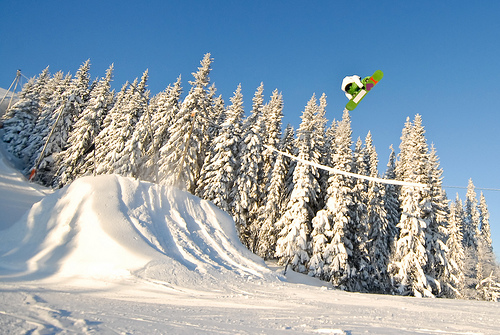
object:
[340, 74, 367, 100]
person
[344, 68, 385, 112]
snowboard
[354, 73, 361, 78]
helmet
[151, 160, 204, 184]
snow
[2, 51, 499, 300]
trees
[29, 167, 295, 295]
ramp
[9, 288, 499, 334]
snow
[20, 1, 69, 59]
sky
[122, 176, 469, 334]
tracks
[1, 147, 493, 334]
slope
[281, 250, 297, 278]
trunk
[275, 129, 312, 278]
tree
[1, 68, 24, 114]
pole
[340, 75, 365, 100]
white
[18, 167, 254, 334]
hill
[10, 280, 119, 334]
lines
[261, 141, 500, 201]
rope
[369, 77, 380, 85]
letter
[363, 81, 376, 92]
heart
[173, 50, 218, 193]
tree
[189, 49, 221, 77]
top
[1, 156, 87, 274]
shadows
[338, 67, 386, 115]
trick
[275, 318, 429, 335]
indents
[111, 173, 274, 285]
impressions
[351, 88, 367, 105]
space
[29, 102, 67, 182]
pole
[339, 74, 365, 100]
jacket